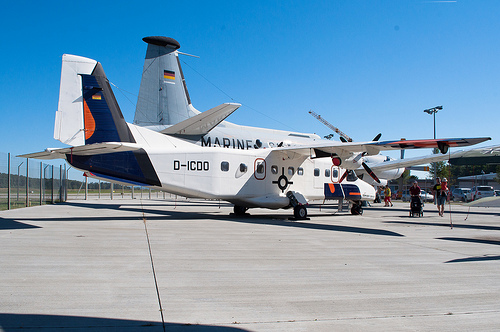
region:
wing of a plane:
[183, 91, 260, 151]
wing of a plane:
[33, 22, 124, 143]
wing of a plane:
[16, 128, 133, 186]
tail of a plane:
[28, 41, 180, 190]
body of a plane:
[192, 101, 328, 218]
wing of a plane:
[379, 107, 494, 162]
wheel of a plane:
[225, 210, 257, 224]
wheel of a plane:
[283, 196, 310, 219]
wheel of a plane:
[345, 202, 372, 217]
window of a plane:
[251, 157, 270, 174]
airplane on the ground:
[15, 52, 483, 227]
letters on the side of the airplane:
[168, 158, 215, 172]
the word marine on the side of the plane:
[201, 134, 256, 148]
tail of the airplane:
[41, 47, 136, 147]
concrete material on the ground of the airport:
[1, 192, 498, 330]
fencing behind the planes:
[1, 150, 75, 209]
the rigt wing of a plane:
[268, 129, 488, 155]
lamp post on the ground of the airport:
[425, 101, 444, 136]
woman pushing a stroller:
[403, 174, 426, 219]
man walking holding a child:
[432, 173, 454, 216]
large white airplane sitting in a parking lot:
[28, 44, 495, 221]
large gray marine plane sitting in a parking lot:
[136, 29, 499, 181]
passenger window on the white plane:
[219, 160, 231, 172]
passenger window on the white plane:
[240, 164, 247, 175]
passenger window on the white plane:
[256, 159, 264, 175]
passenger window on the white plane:
[270, 166, 279, 175]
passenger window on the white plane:
[286, 165, 293, 174]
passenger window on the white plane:
[296, 166, 304, 176]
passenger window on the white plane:
[314, 165, 320, 177]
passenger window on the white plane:
[323, 167, 330, 179]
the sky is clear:
[212, 22, 342, 96]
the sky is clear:
[294, 44, 427, 95]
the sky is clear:
[232, 42, 371, 88]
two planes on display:
[25, 41, 414, 230]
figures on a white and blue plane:
[167, 154, 215, 174]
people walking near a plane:
[378, 169, 467, 223]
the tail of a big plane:
[54, 52, 136, 170]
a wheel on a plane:
[283, 199, 314, 224]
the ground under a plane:
[45, 215, 434, 306]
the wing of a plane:
[282, 128, 477, 155]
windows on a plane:
[211, 159, 342, 179]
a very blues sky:
[47, 6, 467, 45]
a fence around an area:
[5, 148, 84, 204]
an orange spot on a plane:
[77, 98, 102, 138]